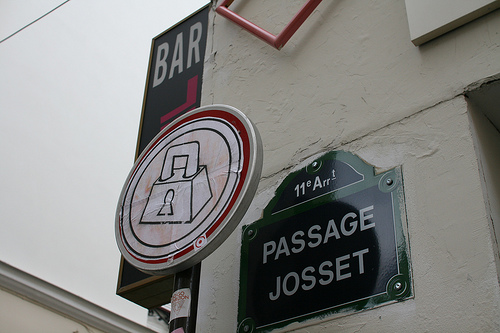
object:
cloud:
[3, 5, 140, 320]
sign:
[114, 104, 264, 276]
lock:
[138, 142, 215, 225]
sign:
[138, 0, 216, 160]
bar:
[150, 22, 204, 89]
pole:
[170, 262, 202, 332]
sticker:
[165, 287, 193, 322]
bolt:
[394, 281, 404, 291]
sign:
[239, 150, 427, 331]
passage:
[264, 204, 386, 268]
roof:
[0, 251, 182, 332]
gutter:
[4, 264, 158, 332]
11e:
[291, 176, 312, 198]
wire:
[0, 0, 71, 46]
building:
[193, 1, 500, 331]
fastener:
[385, 176, 395, 186]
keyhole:
[157, 188, 174, 217]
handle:
[157, 140, 201, 178]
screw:
[242, 324, 249, 332]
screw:
[246, 228, 256, 237]